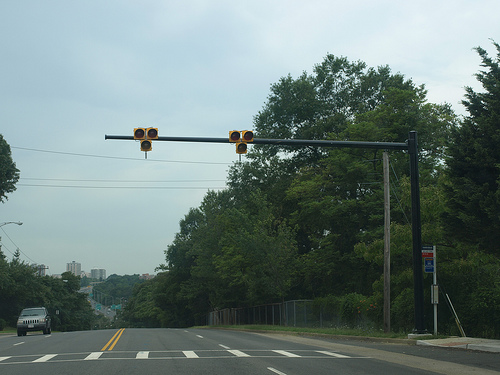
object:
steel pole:
[409, 131, 425, 334]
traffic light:
[229, 130, 254, 154]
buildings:
[139, 273, 150, 280]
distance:
[12, 258, 184, 329]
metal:
[446, 294, 466, 337]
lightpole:
[105, 131, 424, 334]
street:
[0, 327, 500, 375]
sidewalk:
[418, 336, 500, 353]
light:
[134, 127, 158, 151]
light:
[229, 129, 254, 153]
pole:
[104, 131, 424, 333]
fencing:
[206, 300, 377, 329]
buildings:
[35, 261, 107, 279]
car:
[17, 307, 52, 336]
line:
[101, 328, 125, 351]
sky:
[0, 2, 497, 277]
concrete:
[418, 336, 500, 352]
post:
[432, 246, 438, 339]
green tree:
[164, 38, 500, 340]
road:
[0, 328, 500, 375]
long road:
[0, 287, 500, 375]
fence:
[203, 299, 380, 330]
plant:
[301, 292, 381, 329]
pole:
[382, 152, 390, 332]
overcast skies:
[0, 0, 500, 276]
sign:
[421, 245, 434, 272]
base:
[416, 329, 451, 344]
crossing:
[0, 349, 371, 362]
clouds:
[66, 156, 140, 206]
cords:
[388, 178, 455, 318]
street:
[77, 282, 116, 318]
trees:
[0, 241, 95, 331]